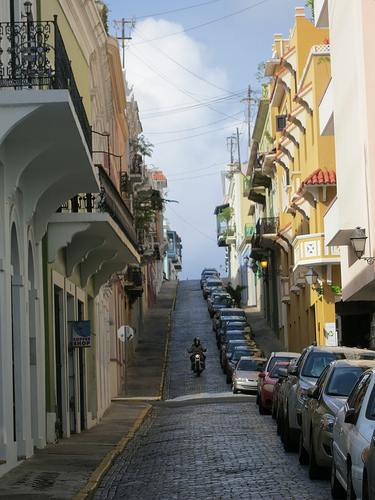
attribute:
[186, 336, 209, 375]
motorcycle — here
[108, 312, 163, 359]
sign — back, stop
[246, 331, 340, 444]
cars — parked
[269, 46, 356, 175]
roof — southwestern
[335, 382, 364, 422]
car — silver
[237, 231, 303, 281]
light — old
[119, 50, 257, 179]
sky — here, present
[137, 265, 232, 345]
road — here, present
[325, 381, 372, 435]
mirror — side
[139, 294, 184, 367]
path — here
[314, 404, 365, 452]
headlight — here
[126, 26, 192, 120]
wires — here, electrical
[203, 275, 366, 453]
vehicles — parked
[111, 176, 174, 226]
flower — here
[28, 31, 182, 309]
building — here, painted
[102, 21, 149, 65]
pole — electric, present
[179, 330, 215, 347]
man — riding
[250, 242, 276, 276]
bulb — here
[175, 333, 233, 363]
motorist — here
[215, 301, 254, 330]
vehicle — here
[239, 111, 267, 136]
post — here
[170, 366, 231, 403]
lump — here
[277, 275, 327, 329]
tree — here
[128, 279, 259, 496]
street — cobblestone, sectioned, narrow, lined, bricks